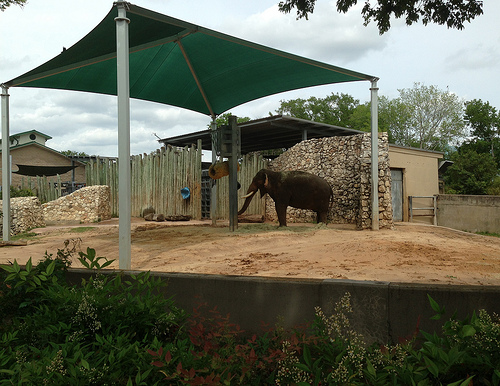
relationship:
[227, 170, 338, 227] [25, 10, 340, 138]
elephant under tent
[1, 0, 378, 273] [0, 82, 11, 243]
canopy by metal pole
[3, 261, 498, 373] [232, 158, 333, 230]
brickwall by elephant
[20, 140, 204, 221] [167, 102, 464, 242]
fence separating building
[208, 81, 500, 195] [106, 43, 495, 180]
tree standing in background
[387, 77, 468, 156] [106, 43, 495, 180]
tree standing in background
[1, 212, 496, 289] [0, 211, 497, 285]
ground covered with dirt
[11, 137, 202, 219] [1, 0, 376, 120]
fence standing under tent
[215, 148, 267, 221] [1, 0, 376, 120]
fence standing under tent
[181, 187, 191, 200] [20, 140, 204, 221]
bucket hanging on fence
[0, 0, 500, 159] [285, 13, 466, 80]
cloud hanging in sky.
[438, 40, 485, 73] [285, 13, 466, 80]
cloud hanging in sky.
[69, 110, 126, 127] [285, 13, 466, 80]
cloud hanging in sky.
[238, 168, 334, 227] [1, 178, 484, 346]
elephant standing in enclosure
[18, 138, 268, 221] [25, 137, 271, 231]
tree limb supporting fencing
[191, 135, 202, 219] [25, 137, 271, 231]
tree limb supporting fencing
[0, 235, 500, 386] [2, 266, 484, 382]
shrub standing in planter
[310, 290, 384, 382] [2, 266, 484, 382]
shrub standing in planter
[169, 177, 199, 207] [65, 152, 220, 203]
bucket hanging on fence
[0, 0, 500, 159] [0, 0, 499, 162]
cloud hanging in sky